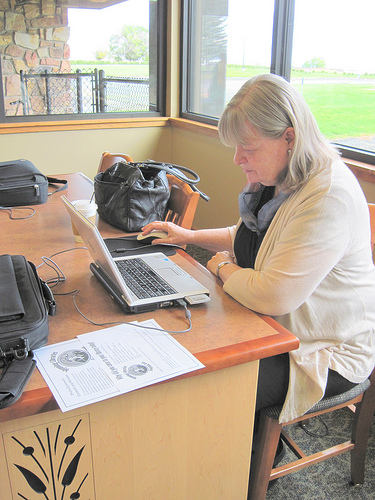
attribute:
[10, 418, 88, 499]
stencil — black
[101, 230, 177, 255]
mousepad — black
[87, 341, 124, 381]
writing — black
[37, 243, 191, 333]
cords — are black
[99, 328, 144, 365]
writing — black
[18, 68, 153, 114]
black fencing — is black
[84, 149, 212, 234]
handbag — is black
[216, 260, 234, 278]
watch — silver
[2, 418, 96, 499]
pattern — black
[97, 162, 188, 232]
handbag — unzipped, leather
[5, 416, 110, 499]
pattern — black 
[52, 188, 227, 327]
keyboard — black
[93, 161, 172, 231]
purse — black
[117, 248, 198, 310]
keyboard — is black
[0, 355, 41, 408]
strap — padded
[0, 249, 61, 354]
bag — black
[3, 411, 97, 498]
pattern — black 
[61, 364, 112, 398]
writing — black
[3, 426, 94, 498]
pattern — black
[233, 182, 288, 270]
scarf — gray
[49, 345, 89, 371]
writing — black